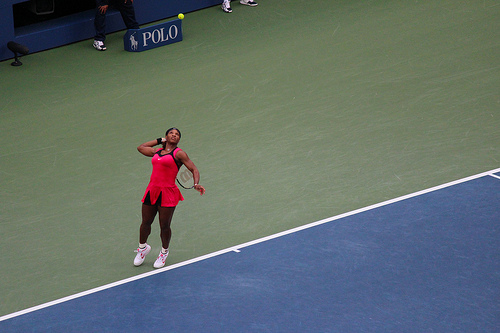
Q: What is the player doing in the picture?
A: Serving.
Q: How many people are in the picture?
A: One.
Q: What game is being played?
A: Tennis.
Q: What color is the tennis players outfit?
A: Pink.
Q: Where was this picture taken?
A: Wimbledon.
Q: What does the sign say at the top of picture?
A: Polo.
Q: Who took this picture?
A: A fan.